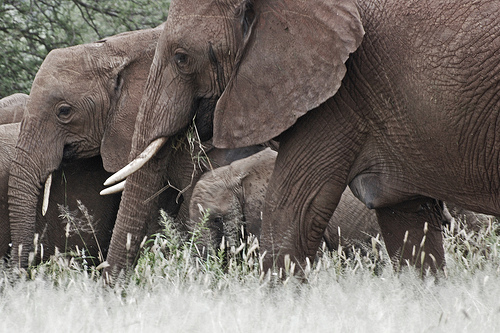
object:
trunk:
[96, 70, 193, 286]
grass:
[157, 205, 222, 284]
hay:
[420, 224, 496, 333]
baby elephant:
[189, 147, 494, 275]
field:
[0, 205, 500, 332]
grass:
[142, 114, 216, 205]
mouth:
[127, 95, 213, 152]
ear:
[211, 1, 367, 150]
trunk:
[7, 120, 64, 277]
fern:
[329, 218, 406, 288]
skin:
[393, 35, 483, 157]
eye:
[54, 102, 74, 124]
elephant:
[8, 25, 281, 283]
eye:
[173, 49, 190, 68]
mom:
[98, 0, 499, 287]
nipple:
[365, 203, 374, 211]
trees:
[0, 2, 172, 99]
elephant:
[92, 0, 499, 283]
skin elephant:
[381, 13, 493, 198]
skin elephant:
[288, 138, 322, 240]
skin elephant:
[175, 160, 191, 230]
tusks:
[102, 136, 167, 186]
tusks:
[100, 180, 126, 197]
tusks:
[41, 172, 54, 217]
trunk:
[192, 225, 220, 263]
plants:
[21, 250, 38, 330]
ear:
[100, 58, 155, 172]